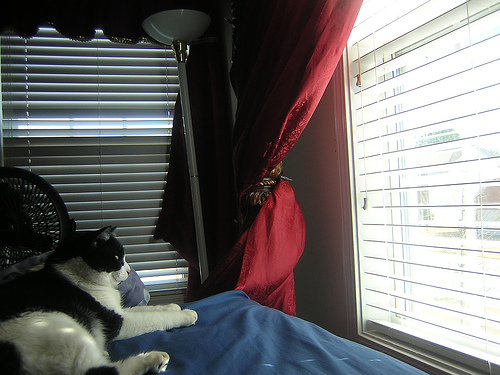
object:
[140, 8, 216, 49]
lamp shade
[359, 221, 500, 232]
cord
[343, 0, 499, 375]
blinds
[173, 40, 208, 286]
bed post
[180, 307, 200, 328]
claws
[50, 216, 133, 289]
head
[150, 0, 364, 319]
red drapes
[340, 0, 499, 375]
window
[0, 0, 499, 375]
room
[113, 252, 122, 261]
eye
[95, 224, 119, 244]
ear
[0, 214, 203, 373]
cat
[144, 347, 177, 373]
paw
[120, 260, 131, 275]
cat's nose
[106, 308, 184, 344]
legs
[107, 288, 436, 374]
sheets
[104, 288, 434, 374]
bed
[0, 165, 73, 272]
fan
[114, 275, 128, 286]
mouth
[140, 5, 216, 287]
lamp